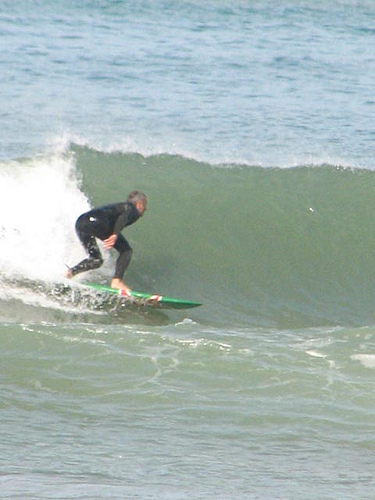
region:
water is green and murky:
[28, 321, 371, 489]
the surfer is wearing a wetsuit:
[67, 199, 140, 278]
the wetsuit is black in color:
[68, 201, 142, 281]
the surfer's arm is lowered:
[104, 204, 138, 250]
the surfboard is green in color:
[58, 275, 201, 314]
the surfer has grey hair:
[126, 188, 146, 204]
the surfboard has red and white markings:
[119, 287, 162, 310]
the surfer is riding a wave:
[46, 188, 202, 314]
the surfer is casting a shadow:
[93, 250, 177, 304]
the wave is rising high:
[14, 133, 373, 345]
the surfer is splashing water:
[9, 147, 114, 314]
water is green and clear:
[22, 322, 371, 478]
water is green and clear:
[56, 369, 256, 477]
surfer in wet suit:
[54, 180, 169, 284]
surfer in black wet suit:
[55, 183, 164, 278]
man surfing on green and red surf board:
[14, 268, 219, 326]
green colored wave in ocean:
[145, 160, 282, 285]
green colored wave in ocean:
[224, 182, 365, 319]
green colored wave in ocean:
[9, 354, 169, 484]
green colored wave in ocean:
[154, 341, 342, 480]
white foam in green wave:
[7, 163, 72, 259]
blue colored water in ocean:
[19, 21, 177, 129]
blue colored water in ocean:
[187, 21, 356, 126]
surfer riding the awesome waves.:
[12, 120, 246, 346]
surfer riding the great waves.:
[8, 150, 253, 341]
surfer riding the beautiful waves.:
[12, 105, 267, 350]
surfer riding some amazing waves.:
[15, 123, 245, 336]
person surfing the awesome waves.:
[15, 141, 222, 339]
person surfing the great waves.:
[18, 114, 236, 342]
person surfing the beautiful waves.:
[15, 117, 235, 330]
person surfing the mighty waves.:
[1, 96, 243, 327]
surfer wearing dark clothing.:
[56, 180, 170, 310]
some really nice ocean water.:
[36, 313, 316, 469]